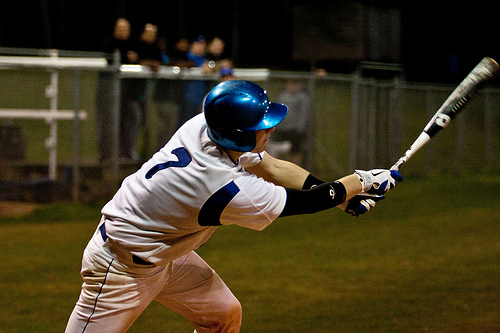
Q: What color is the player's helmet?
A: Blue.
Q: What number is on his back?
A: 7.